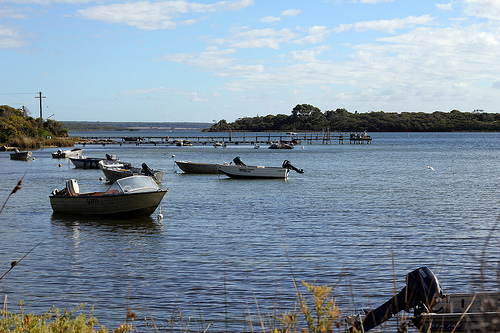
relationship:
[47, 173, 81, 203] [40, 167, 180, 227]
engine on boat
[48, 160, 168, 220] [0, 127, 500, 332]
boat on lake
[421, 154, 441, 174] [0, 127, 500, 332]
bird on lake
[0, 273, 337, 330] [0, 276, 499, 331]
plants are on shore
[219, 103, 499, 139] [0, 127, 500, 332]
peninsula extending into lake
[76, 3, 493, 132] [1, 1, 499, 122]
clouds are in sky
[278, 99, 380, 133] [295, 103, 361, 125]
trees has leaves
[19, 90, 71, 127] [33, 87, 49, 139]
power lines are on electrical pole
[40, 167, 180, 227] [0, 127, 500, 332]
boat in lake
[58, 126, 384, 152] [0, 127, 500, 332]
dock in lake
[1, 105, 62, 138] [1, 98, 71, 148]
shrubs are in hillside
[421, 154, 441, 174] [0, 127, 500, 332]
bird flying over lake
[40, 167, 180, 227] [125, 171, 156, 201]
boat has window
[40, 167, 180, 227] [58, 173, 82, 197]
boat has engine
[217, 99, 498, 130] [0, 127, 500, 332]
trees are next to lake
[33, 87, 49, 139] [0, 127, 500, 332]
electrical pole close to lake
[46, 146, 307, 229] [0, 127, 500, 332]
boats are in lake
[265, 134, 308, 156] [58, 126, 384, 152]
boats are next to dock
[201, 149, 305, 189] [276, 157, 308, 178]
boat has motor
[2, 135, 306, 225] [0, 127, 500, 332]
boats are in lake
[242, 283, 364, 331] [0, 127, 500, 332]
grass are growing by lake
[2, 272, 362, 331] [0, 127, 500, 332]
weeds are growing by lake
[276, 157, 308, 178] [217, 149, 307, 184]
motor on boat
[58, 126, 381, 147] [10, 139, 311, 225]
dock for boat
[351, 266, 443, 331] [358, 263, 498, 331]
motor for boat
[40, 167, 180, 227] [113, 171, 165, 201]
boat has window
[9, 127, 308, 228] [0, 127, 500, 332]
boats are parked in lake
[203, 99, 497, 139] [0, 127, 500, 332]
trees are off lake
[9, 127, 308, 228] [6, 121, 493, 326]
boats are in lake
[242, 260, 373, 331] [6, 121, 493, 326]
grass next to lake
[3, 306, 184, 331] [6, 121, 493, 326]
weeds next to lake